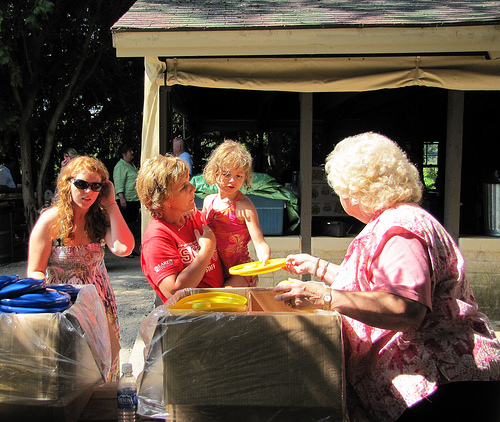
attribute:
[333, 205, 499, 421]
shirt — flowery, pink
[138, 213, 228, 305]
shirt — red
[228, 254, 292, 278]
frisbee — yellow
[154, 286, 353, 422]
box — cardboard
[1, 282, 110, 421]
box — cardboard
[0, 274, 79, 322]
frisbees — blue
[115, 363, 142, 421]
water bottle — plastic, clear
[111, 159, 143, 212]
shirt — green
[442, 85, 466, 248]
post — wooden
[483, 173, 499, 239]
trashcan — metal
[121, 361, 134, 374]
cap — white